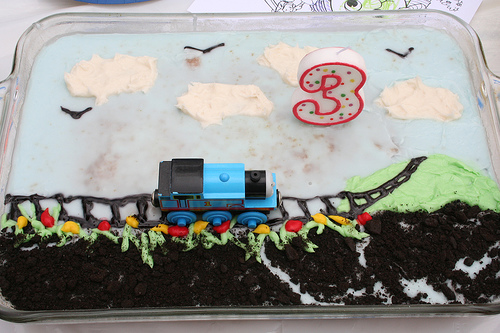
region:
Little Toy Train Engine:
[148, 157, 282, 229]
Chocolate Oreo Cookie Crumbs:
[3, 197, 498, 311]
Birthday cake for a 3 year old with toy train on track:
[2, 1, 497, 329]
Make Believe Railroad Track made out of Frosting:
[1, 152, 497, 237]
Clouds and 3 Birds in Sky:
[55, 37, 466, 132]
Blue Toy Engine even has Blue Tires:
[147, 152, 277, 232]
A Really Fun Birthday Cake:
[0, 0, 492, 330]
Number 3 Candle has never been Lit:
[290, 40, 370, 140]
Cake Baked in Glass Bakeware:
[0, 0, 495, 330]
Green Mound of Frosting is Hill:
[333, 151, 498, 215]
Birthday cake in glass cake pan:
[3, 8, 495, 320]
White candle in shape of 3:
[286, 38, 373, 130]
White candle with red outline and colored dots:
[292, 43, 373, 133]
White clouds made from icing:
[175, 79, 273, 130]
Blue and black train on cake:
[155, 154, 285, 233]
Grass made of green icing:
[353, 153, 486, 213]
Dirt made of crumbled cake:
[2, 242, 494, 300]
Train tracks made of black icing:
[10, 190, 142, 225]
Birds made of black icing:
[58, 101, 94, 123]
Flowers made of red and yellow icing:
[12, 211, 172, 237]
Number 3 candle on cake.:
[293, 37, 353, 140]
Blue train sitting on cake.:
[167, 153, 296, 230]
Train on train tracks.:
[44, 188, 356, 226]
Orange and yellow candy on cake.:
[41, 207, 363, 232]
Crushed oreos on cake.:
[78, 238, 375, 290]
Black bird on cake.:
[53, 100, 98, 120]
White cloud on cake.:
[88, 48, 148, 117]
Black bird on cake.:
[178, 33, 230, 64]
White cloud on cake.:
[191, 70, 275, 127]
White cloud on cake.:
[386, 78, 466, 131]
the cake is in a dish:
[5, 2, 495, 320]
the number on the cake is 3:
[248, 30, 398, 140]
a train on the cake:
[118, 133, 310, 244]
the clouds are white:
[31, 35, 268, 148]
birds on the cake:
[40, 27, 243, 138]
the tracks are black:
[10, 165, 334, 246]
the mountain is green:
[325, 121, 486, 231]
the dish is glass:
[3, 4, 491, 327]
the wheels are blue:
[159, 204, 276, 242]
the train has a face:
[260, 160, 285, 205]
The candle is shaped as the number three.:
[288, 45, 368, 126]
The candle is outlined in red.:
[286, 45, 366, 125]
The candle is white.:
[285, 45, 365, 125]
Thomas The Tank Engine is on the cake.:
[153, 153, 281, 229]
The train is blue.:
[155, 155, 281, 230]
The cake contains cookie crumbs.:
[0, 195, 495, 310]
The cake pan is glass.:
[0, 10, 495, 322]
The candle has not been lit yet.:
[288, 44, 370, 126]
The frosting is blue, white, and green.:
[6, 28, 498, 246]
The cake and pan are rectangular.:
[1, 7, 498, 321]